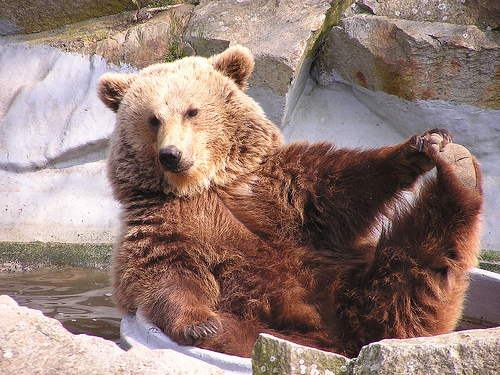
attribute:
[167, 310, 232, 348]
paws — bear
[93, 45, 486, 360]
hair — brown 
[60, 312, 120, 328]
ripples — small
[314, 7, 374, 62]
rocks — large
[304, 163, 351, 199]
hair — brown 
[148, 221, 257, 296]
fur — dark and brown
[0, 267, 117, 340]
ripples — small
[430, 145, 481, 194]
foot — brown, large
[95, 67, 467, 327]
bear — furry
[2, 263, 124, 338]
water — dirty 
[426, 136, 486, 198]
paw — large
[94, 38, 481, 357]
bear — brown, grizzly, furry, bushy, Small 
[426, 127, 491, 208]
foot — bear's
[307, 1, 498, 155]
rock — large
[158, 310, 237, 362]
claws — brown, pointy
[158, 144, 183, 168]
snout — black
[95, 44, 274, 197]
head — furry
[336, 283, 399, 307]
patch — Small 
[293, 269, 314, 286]
patch — Small 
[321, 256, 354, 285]
patch — Small 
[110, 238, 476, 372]
tub — round, cement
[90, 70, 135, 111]
ear — large, furry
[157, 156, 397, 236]
fur — dark and brown